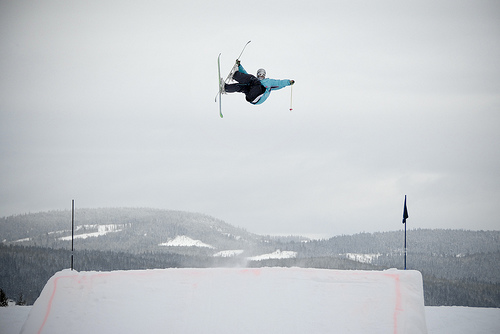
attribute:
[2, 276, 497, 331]
snow — small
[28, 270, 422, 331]
ramp — steep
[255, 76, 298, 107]
jacket — blue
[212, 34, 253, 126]
skis — white, odd position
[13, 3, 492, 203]
air — white, gray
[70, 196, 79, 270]
pole — black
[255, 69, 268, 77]
helmet — grey, silver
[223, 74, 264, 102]
pants — black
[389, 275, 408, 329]
line — red